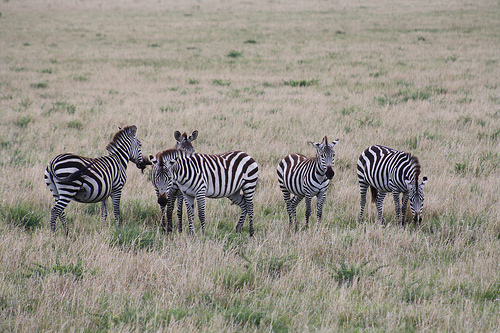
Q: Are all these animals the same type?
A: Yes, all the animals are zebras.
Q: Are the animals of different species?
A: No, all the animals are zebras.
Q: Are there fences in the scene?
A: No, there are no fences.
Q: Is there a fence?
A: No, there are no fences.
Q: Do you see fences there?
A: No, there are no fences.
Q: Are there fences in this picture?
A: No, there are no fences.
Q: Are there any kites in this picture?
A: No, there are no kites.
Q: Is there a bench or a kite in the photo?
A: No, there are no kites or benches.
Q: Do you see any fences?
A: No, there are no fences.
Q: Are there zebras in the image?
A: Yes, there is a zebra.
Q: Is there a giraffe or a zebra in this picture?
A: Yes, there is a zebra.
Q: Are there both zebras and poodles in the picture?
A: No, there is a zebra but no poodles.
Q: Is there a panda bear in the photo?
A: No, there are no panda bears.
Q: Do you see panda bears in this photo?
A: No, there are no panda bears.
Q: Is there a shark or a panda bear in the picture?
A: No, there are no panda bears or sharks.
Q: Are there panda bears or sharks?
A: No, there are no panda bears or sharks.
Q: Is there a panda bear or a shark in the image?
A: No, there are no panda bears or sharks.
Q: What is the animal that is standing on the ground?
A: The animal is a zebra.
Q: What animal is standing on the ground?
A: The animal is a zebra.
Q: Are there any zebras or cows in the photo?
A: Yes, there is a zebra.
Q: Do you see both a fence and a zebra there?
A: No, there is a zebra but no fences.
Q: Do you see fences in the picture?
A: No, there are no fences.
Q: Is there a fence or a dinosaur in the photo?
A: No, there are no fences or dinosaurs.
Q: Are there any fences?
A: No, there are no fences.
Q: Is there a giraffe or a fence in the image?
A: No, there are no fences or giraffes.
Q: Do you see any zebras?
A: Yes, there is a zebra.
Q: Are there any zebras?
A: Yes, there is a zebra.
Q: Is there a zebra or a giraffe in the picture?
A: Yes, there is a zebra.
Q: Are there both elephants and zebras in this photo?
A: No, there is a zebra but no elephants.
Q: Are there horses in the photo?
A: No, there are no horses.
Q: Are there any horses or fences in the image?
A: No, there are no horses or fences.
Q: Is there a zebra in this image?
A: Yes, there is a zebra.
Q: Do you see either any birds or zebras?
A: Yes, there is a zebra.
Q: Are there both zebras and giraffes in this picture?
A: No, there is a zebra but no giraffes.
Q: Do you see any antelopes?
A: No, there are no antelopes.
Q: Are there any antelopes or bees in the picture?
A: No, there are no antelopes or bees.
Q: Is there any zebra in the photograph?
A: Yes, there is a zebra.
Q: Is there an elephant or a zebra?
A: Yes, there is a zebra.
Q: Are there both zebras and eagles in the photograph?
A: No, there is a zebra but no eagles.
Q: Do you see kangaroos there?
A: No, there are no kangaroos.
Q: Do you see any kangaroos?
A: No, there are no kangaroos.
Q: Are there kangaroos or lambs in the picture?
A: No, there are no kangaroos or lambs.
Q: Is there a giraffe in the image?
A: No, there are no giraffes.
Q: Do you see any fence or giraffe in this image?
A: No, there are no giraffes or fences.